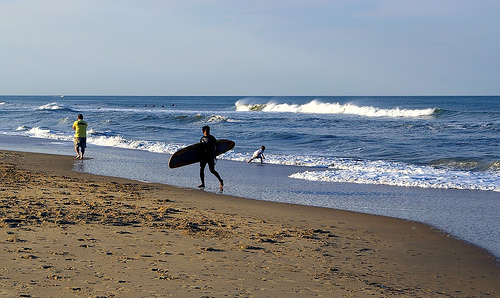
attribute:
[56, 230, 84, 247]
sand — brown, wet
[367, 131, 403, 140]
water — wet, blue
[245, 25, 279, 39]
sky — cloudy